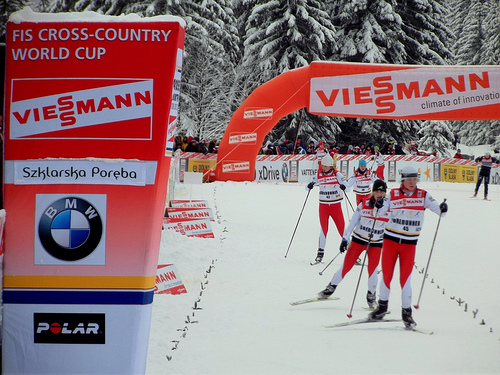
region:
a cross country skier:
[359, 160, 449, 335]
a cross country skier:
[302, 175, 391, 315]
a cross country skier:
[347, 160, 381, 212]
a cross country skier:
[284, 155, 347, 265]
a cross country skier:
[464, 148, 496, 200]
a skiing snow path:
[164, 170, 498, 369]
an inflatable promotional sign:
[205, 56, 498, 176]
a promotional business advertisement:
[10, 73, 155, 145]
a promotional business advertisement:
[5, 161, 148, 186]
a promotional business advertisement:
[33, 189, 103, 260]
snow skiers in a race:
[299, 143, 457, 329]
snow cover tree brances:
[260, 15, 327, 54]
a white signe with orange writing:
[314, 75, 498, 121]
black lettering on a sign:
[24, 162, 141, 186]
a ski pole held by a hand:
[286, 178, 323, 265]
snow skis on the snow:
[331, 308, 401, 331]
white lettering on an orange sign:
[8, 26, 167, 68]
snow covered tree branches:
[189, 83, 215, 125]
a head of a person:
[396, 161, 428, 196]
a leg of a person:
[395, 255, 423, 314]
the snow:
[263, 295, 311, 372]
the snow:
[261, 317, 326, 362]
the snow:
[239, 274, 317, 374]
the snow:
[245, 308, 293, 365]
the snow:
[281, 333, 294, 365]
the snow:
[201, 247, 281, 365]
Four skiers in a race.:
[196, 17, 488, 372]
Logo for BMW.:
[26, 187, 124, 269]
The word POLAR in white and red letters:
[17, 308, 117, 348]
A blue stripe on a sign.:
[6, 285, 160, 308]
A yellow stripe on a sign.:
[1, 270, 161, 295]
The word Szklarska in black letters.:
[16, 159, 97, 183]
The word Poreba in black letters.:
[89, 164, 148, 184]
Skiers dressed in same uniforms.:
[286, 125, 468, 343]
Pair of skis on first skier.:
[323, 297, 446, 349]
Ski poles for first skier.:
[338, 191, 455, 331]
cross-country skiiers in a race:
[300, 148, 450, 339]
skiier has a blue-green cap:
[344, 153, 384, 212]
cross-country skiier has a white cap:
[386, 164, 446, 334]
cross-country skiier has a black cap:
[316, 175, 391, 312]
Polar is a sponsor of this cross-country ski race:
[20, 305, 127, 358]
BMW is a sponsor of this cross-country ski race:
[25, 189, 125, 268]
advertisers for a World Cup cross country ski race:
[3, 44, 165, 373]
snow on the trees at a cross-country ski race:
[185, 45, 497, 147]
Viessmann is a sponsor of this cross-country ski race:
[293, 53, 497, 132]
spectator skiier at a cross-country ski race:
[466, 145, 498, 207]